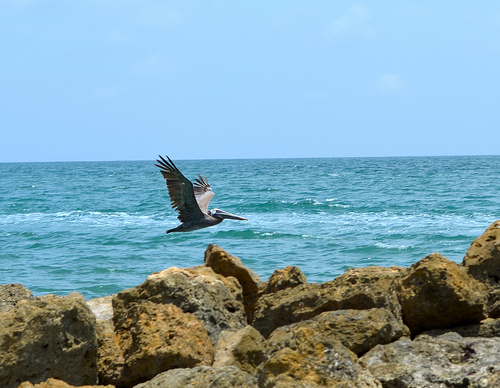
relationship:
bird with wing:
[153, 154, 244, 234] [153, 153, 204, 221]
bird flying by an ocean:
[153, 154, 244, 234] [3, 159, 493, 310]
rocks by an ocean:
[118, 275, 479, 375] [21, 152, 476, 264]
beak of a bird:
[222, 216, 244, 223] [153, 154, 244, 234]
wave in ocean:
[17, 205, 147, 236] [1, 161, 454, 253]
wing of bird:
[151, 151, 199, 222] [150, 152, 252, 234]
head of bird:
[204, 205, 251, 225] [133, 156, 258, 244]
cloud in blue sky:
[0, 0, 500, 162] [0, 0, 499, 163]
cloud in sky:
[0, 0, 500, 162] [2, 0, 496, 161]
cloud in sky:
[361, 68, 408, 101] [2, 0, 496, 161]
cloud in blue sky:
[0, 0, 500, 162] [1, 1, 496, 158]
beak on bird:
[224, 211, 249, 220] [150, 152, 252, 234]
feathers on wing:
[156, 169, 185, 219] [152, 148, 203, 223]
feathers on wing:
[192, 174, 208, 204] [187, 172, 214, 215]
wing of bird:
[152, 148, 203, 223] [155, 150, 246, 237]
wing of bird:
[187, 172, 214, 215] [155, 150, 246, 237]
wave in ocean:
[0, 205, 498, 234] [3, 159, 493, 310]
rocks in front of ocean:
[157, 272, 354, 331] [3, 159, 493, 310]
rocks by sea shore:
[93, 259, 498, 376] [4, 224, 494, 311]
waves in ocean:
[240, 194, 355, 218] [3, 159, 493, 310]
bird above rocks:
[151, 152, 248, 234] [0, 222, 498, 379]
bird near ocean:
[151, 152, 248, 234] [3, 159, 493, 310]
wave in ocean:
[0, 205, 498, 234] [3, 148, 499, 280]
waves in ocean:
[15, 165, 107, 205] [3, 148, 499, 280]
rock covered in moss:
[407, 269, 481, 332] [414, 278, 464, 325]